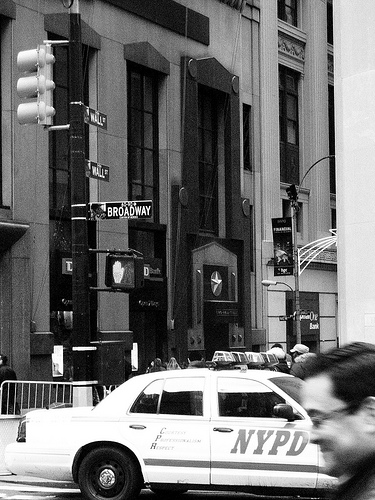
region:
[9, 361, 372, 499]
The police car is white.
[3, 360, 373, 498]
New York city police car.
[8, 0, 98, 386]
The traffic light is on a pole.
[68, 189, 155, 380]
The street sign is on a pole.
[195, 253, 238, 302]
There's a large star on the building.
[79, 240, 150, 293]
Hand signal on light.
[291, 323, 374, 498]
The man is wearing glasses.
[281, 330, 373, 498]
The man is moving.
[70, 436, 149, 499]
The car has a tire.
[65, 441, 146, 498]
The tire is round.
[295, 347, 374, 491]
a man wearing eyeglasses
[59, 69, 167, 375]
street signs attached on the pole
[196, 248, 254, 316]
a star logo on the building door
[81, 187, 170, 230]
street sign says Broadway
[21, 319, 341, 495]
police car in the street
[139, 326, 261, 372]
people walking at the sidewalk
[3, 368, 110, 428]
a metal fence on sidewalk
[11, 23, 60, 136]
a traffic light attached to a pole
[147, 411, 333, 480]
NYPD written on the car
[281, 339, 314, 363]
a man wearing a cap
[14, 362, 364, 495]
a white police car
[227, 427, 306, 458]
NYPD logo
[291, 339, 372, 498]
a blurry man walking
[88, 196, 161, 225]
a street sign labeled BROADWAY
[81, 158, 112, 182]
a street signed labeled WALL ST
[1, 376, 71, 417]
portable metal fencing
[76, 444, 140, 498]
a car's rear right tire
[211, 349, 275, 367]
a police car's emergency lights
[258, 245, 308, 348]
a tall street light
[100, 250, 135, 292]
an electronic crosswalk sign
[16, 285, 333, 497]
a police car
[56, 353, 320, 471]
a police car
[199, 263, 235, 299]
silver star logo on building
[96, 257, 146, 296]
hands on the traffic signal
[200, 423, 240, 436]
black door opener on car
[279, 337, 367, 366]
part in man's black hair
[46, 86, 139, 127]
black and white street sign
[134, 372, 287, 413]
shiny glass in car window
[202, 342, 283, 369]
rows of lights on top of car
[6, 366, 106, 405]
large silver barrier on side walk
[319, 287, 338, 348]
large cement bricks on wall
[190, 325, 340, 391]
people walking in the street